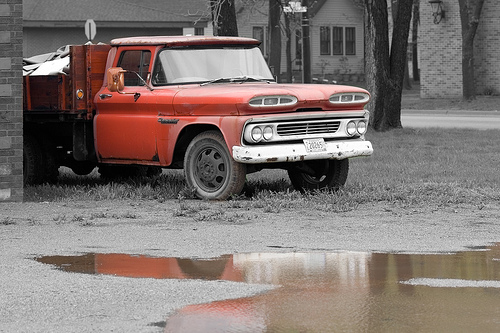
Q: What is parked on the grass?
A: Truck.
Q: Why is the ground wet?
A: Rain.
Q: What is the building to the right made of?
A: Brick.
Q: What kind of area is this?
A: Suburban.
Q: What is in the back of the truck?
A: Junk.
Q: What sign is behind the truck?
A: Stop sign.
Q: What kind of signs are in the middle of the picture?
A: Street.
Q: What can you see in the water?
A: Truck reflection?.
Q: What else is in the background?
A: Tree.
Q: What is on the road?
A: Puddle.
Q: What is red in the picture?
A: A truck.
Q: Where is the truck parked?
A: The driveway.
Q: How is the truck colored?
A: Orange.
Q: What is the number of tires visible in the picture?
A: Three.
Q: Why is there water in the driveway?
A: It probably rained.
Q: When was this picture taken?
A: During the day.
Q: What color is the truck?
A: Red.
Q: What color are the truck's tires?
A: Black.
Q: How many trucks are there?
A: One.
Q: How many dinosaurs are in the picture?
A: Zero.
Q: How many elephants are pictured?
A: Zero.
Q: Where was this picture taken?
A: On the street.